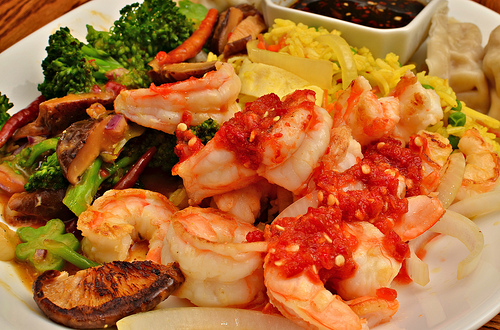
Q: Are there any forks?
A: No, there are no forks.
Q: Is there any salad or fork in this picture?
A: No, there are no forks or salad.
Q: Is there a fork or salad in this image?
A: No, there are no forks or salad.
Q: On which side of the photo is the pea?
A: The pea is on the right of the image.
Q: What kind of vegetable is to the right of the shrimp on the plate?
A: The vegetable is a pea.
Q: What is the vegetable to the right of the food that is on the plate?
A: The vegetable is a pea.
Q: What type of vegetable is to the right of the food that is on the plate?
A: The vegetable is a pea.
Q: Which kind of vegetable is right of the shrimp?
A: The vegetable is a pea.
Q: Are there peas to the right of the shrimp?
A: Yes, there is a pea to the right of the shrimp.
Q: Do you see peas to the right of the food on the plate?
A: Yes, there is a pea to the right of the shrimp.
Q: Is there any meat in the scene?
A: Yes, there is meat.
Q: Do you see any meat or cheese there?
A: Yes, there is meat.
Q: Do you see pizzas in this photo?
A: No, there are no pizzas.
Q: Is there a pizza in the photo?
A: No, there are no pizzas.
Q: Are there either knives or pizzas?
A: No, there are no pizzas or knives.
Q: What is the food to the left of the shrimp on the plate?
A: The food is meat.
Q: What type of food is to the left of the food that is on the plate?
A: The food is meat.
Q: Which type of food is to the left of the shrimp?
A: The food is meat.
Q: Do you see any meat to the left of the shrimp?
A: Yes, there is meat to the left of the shrimp.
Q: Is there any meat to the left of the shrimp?
A: Yes, there is meat to the left of the shrimp.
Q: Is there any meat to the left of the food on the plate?
A: Yes, there is meat to the left of the shrimp.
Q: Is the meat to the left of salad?
A: No, the meat is to the left of the shrimp.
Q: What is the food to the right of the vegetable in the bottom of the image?
A: The food is meat.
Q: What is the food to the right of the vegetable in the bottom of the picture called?
A: The food is meat.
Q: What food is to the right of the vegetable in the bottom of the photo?
A: The food is meat.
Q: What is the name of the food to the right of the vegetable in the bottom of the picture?
A: The food is meat.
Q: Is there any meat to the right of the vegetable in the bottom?
A: Yes, there is meat to the right of the vegetable.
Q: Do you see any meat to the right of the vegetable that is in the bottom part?
A: Yes, there is meat to the right of the vegetable.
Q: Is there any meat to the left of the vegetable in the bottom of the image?
A: No, the meat is to the right of the vegetable.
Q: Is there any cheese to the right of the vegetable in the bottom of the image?
A: No, there is meat to the right of the vegetable.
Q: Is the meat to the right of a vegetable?
A: Yes, the meat is to the right of a vegetable.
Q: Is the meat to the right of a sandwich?
A: No, the meat is to the right of a vegetable.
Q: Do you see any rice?
A: Yes, there is rice.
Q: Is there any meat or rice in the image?
A: Yes, there is rice.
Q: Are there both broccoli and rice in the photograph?
A: Yes, there are both rice and broccoli.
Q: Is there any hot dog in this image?
A: No, there are no hot dogs.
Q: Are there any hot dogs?
A: No, there are no hot dogs.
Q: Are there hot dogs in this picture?
A: No, there are no hot dogs.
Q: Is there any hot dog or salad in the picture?
A: No, there are no hot dogs or salad.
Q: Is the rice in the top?
A: Yes, the rice is in the top of the image.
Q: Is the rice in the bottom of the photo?
A: No, the rice is in the top of the image.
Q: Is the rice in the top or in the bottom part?
A: The rice is in the top of the image.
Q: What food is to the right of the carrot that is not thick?
A: The food is rice.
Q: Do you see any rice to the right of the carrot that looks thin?
A: Yes, there is rice to the right of the carrot.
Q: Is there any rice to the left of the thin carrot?
A: No, the rice is to the right of the carrot.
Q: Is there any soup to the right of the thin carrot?
A: No, there is rice to the right of the carrot.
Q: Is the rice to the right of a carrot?
A: Yes, the rice is to the right of a carrot.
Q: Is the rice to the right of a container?
A: No, the rice is to the right of a carrot.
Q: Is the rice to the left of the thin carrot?
A: No, the rice is to the right of the carrot.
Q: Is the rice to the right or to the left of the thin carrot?
A: The rice is to the right of the carrot.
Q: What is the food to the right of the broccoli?
A: The food is rice.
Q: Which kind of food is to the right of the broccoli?
A: The food is rice.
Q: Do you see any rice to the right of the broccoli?
A: Yes, there is rice to the right of the broccoli.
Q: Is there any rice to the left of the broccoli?
A: No, the rice is to the right of the broccoli.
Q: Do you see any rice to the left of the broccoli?
A: No, the rice is to the right of the broccoli.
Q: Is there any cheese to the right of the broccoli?
A: No, there is rice to the right of the broccoli.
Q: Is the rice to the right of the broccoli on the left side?
A: Yes, the rice is to the right of the broccoli.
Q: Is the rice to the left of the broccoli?
A: No, the rice is to the right of the broccoli.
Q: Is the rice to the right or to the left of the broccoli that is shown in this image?
A: The rice is to the right of the broccoli.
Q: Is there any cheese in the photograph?
A: No, there is no cheese.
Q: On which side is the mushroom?
A: The mushroom is on the left of the image.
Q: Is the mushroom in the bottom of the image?
A: Yes, the mushroom is in the bottom of the image.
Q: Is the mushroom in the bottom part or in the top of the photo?
A: The mushroom is in the bottom of the image.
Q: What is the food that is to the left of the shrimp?
A: The food is a mushroom.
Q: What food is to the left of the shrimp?
A: The food is a mushroom.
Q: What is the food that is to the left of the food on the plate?
A: The food is a mushroom.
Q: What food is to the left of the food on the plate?
A: The food is a mushroom.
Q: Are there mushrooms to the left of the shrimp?
A: Yes, there is a mushroom to the left of the shrimp.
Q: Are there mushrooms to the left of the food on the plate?
A: Yes, there is a mushroom to the left of the shrimp.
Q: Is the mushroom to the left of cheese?
A: No, the mushroom is to the left of the shrimp.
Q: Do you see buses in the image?
A: No, there are no buses.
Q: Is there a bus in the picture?
A: No, there are no buses.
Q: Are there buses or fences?
A: No, there are no buses or fences.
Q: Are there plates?
A: Yes, there is a plate.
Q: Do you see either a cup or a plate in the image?
A: Yes, there is a plate.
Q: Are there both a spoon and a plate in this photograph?
A: No, there is a plate but no spoons.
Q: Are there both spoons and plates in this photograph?
A: No, there is a plate but no spoons.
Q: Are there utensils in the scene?
A: No, there are no utensils.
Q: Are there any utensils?
A: No, there are no utensils.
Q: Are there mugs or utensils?
A: No, there are no utensils or mugs.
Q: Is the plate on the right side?
A: Yes, the plate is on the right of the image.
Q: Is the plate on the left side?
A: No, the plate is on the right of the image.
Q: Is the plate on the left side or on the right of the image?
A: The plate is on the right of the image.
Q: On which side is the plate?
A: The plate is on the right of the image.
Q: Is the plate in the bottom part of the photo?
A: Yes, the plate is in the bottom of the image.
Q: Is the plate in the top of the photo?
A: No, the plate is in the bottom of the image.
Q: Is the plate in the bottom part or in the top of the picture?
A: The plate is in the bottom of the image.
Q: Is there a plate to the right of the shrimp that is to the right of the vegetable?
A: Yes, there is a plate to the right of the shrimp.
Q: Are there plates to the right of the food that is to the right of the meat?
A: Yes, there is a plate to the right of the shrimp.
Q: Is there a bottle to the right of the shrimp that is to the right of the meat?
A: No, there is a plate to the right of the shrimp.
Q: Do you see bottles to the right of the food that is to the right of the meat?
A: No, there is a plate to the right of the shrimp.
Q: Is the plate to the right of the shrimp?
A: Yes, the plate is to the right of the shrimp.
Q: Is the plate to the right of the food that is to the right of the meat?
A: Yes, the plate is to the right of the shrimp.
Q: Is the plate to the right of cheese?
A: No, the plate is to the right of the shrimp.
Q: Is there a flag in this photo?
A: No, there are no flags.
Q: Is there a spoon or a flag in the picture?
A: No, there are no flags or spoons.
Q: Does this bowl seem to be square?
A: Yes, the bowl is square.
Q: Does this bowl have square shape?
A: Yes, the bowl is square.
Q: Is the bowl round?
A: No, the bowl is square.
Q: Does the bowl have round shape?
A: No, the bowl is square.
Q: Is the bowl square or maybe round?
A: The bowl is square.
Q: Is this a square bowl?
A: Yes, this is a square bowl.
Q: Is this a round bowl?
A: No, this is a square bowl.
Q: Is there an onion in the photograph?
A: Yes, there is an onion.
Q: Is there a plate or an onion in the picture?
A: Yes, there is an onion.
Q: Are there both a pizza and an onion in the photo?
A: No, there is an onion but no pizzas.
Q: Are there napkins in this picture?
A: No, there are no napkins.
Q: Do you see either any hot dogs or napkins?
A: No, there are no napkins or hot dogs.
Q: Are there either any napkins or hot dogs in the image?
A: No, there are no napkins or hot dogs.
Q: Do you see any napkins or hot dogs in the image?
A: No, there are no napkins or hot dogs.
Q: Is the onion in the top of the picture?
A: Yes, the onion is in the top of the image.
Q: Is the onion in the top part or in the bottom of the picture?
A: The onion is in the top of the image.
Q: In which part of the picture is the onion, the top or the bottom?
A: The onion is in the top of the image.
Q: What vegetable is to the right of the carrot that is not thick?
A: The vegetable is an onion.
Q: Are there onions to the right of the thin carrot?
A: Yes, there is an onion to the right of the carrot.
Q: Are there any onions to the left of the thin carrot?
A: No, the onion is to the right of the carrot.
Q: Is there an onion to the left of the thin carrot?
A: No, the onion is to the right of the carrot.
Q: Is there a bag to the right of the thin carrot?
A: No, there is an onion to the right of the carrot.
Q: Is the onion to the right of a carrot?
A: Yes, the onion is to the right of a carrot.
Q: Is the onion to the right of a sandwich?
A: No, the onion is to the right of a carrot.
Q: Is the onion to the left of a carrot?
A: No, the onion is to the right of a carrot.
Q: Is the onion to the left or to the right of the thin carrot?
A: The onion is to the right of the carrot.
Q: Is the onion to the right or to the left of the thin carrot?
A: The onion is to the right of the carrot.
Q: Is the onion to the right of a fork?
A: No, the onion is to the right of the carrot.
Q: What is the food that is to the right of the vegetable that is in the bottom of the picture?
A: The food is shrimp.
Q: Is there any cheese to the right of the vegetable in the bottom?
A: No, there is shrimp to the right of the vegetable.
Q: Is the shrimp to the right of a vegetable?
A: Yes, the shrimp is to the right of a vegetable.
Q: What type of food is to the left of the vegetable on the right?
A: The food is shrimp.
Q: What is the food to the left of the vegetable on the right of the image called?
A: The food is shrimp.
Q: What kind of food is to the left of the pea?
A: The food is shrimp.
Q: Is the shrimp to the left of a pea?
A: Yes, the shrimp is to the left of a pea.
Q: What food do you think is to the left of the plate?
A: The food is shrimp.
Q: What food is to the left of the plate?
A: The food is shrimp.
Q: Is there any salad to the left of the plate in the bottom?
A: No, there is shrimp to the left of the plate.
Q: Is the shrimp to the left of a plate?
A: Yes, the shrimp is to the left of a plate.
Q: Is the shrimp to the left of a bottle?
A: No, the shrimp is to the left of a plate.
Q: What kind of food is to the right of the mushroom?
A: The food is shrimp.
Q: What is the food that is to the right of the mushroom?
A: The food is shrimp.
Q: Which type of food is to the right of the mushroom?
A: The food is shrimp.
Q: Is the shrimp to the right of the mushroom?
A: Yes, the shrimp is to the right of the mushroom.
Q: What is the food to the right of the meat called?
A: The food is shrimp.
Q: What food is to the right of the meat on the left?
A: The food is shrimp.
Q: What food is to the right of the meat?
A: The food is shrimp.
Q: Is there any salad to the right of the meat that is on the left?
A: No, there is shrimp to the right of the meat.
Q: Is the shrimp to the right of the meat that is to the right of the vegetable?
A: Yes, the shrimp is to the right of the meat.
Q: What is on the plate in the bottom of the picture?
A: The shrimp is on the plate.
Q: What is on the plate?
A: The shrimp is on the plate.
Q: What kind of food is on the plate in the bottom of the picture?
A: The food is shrimp.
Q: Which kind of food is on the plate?
A: The food is shrimp.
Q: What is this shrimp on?
A: The shrimp is on the plate.